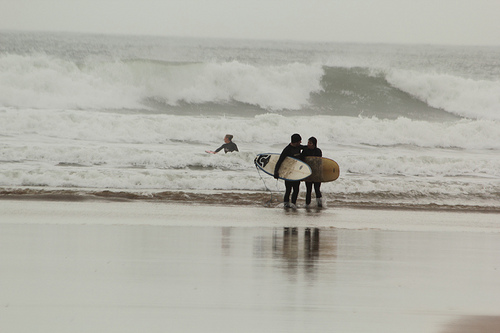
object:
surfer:
[273, 134, 306, 210]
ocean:
[1, 30, 499, 235]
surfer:
[299, 137, 322, 209]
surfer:
[211, 134, 238, 154]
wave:
[2, 51, 326, 112]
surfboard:
[254, 152, 312, 181]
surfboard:
[299, 156, 339, 182]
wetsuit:
[273, 144, 307, 204]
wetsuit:
[300, 145, 323, 205]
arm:
[299, 144, 309, 149]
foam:
[2, 52, 326, 116]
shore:
[1, 196, 499, 331]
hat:
[273, 194, 283, 203]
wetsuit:
[215, 142, 238, 155]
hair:
[244, 161, 252, 167]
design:
[257, 154, 271, 167]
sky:
[0, 2, 499, 47]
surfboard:
[203, 149, 215, 156]